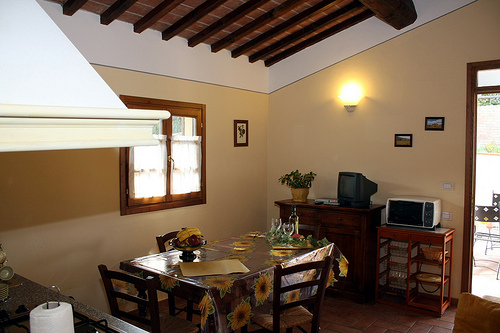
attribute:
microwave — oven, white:
[380, 194, 445, 232]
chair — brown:
[247, 254, 335, 333]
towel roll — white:
[24, 281, 76, 332]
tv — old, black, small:
[334, 167, 380, 210]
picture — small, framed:
[422, 114, 450, 132]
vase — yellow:
[290, 187, 310, 204]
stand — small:
[370, 224, 456, 318]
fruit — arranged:
[168, 224, 210, 252]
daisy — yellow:
[223, 298, 256, 331]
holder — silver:
[44, 279, 63, 308]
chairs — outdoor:
[475, 189, 500, 282]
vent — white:
[0, 1, 173, 159]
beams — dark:
[60, 2, 424, 70]